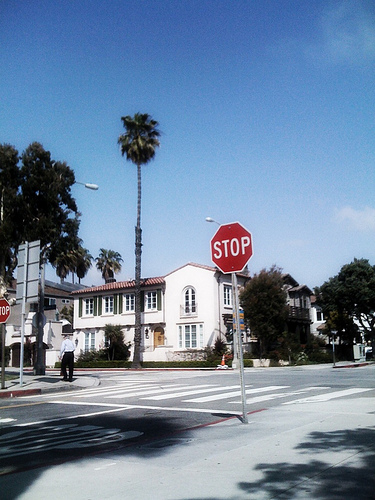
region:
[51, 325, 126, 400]
the man is wearing white sleeves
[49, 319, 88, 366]
the man is wearing white sleeves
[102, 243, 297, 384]
the house is white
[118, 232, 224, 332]
the house is white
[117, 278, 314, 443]
the house is white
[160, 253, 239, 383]
the house is white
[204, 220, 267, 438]
stop sign at an intersection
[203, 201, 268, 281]
stop sign is red and white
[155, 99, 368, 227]
the sky is cloudless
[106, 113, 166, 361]
palm tree is tall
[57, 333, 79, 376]
old man on the sidewalk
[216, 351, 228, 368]
orange traffic cone on sidewalk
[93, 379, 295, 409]
crossing walk is painted white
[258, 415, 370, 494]
shadow of trees on sidewalk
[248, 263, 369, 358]
trees in front of building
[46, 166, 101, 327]
street lights are off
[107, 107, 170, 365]
palm tree in front of building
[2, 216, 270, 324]
two stop signs on the street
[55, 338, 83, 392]
man walking on sidewalk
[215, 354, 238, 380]
orange cone with white stripe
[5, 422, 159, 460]
stop written on the street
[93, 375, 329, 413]
white lines on the road for street crossing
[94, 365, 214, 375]
the curve is painted red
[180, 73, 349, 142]
sky is blue with a few clouds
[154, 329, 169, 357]
door is made of wood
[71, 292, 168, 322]
green shutters on the windows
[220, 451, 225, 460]
the pavement is grey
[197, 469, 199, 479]
the pavement is grey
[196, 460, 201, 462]
the pavement is grey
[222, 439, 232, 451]
the pavement is grey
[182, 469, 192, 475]
the pavement is grey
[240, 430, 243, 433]
the pavement is grey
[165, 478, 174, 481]
the pavement is grey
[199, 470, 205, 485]
the pavement is grey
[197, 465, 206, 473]
the pavement is grey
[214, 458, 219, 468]
the pavement is grey